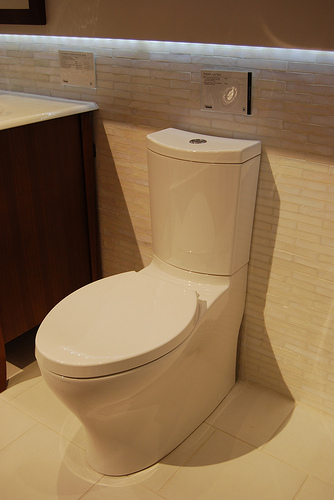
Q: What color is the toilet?
A: White.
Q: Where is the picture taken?
A: In a bathroom.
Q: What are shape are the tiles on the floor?
A: Square.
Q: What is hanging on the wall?
A: A mirror.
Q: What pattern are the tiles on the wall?
A: Horizontal.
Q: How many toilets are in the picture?
A: One.